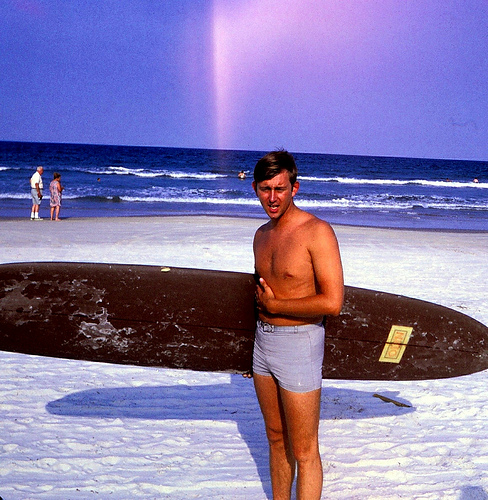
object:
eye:
[259, 187, 270, 192]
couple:
[29, 166, 63, 221]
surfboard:
[0, 261, 487, 381]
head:
[252, 146, 300, 218]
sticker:
[377, 324, 413, 364]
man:
[252, 147, 345, 500]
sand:
[0, 219, 488, 500]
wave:
[0, 165, 488, 210]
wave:
[342, 192, 475, 201]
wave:
[0, 165, 227, 180]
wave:
[293, 176, 488, 190]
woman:
[49, 172, 64, 221]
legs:
[250, 372, 323, 500]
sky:
[0, 0, 488, 161]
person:
[238, 170, 247, 178]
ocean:
[0, 141, 488, 234]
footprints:
[367, 426, 444, 479]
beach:
[0, 215, 487, 500]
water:
[0, 139, 487, 230]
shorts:
[252, 320, 325, 394]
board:
[0, 261, 486, 380]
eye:
[259, 186, 271, 191]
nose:
[269, 189, 277, 202]